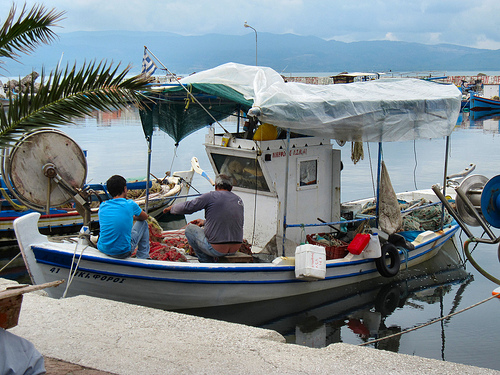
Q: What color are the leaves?
A: Green.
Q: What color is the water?
A: Blue.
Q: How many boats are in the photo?
A: 3.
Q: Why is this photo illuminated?
A: Sunlight.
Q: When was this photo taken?
A: During the day.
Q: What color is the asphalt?
A: Gray.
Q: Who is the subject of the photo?
A: The boat.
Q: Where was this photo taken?
A: In a marina.